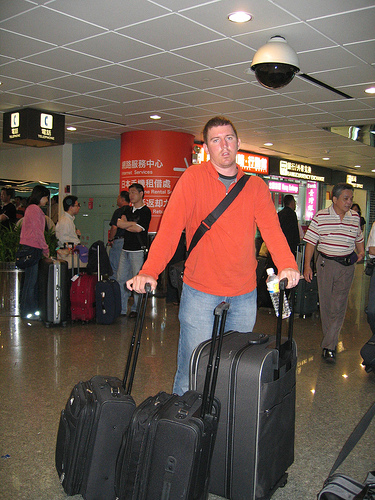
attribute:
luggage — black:
[54, 281, 152, 499]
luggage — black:
[113, 300, 229, 499]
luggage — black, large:
[188, 277, 298, 500]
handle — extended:
[122, 280, 153, 392]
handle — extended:
[199, 300, 229, 420]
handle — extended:
[274, 278, 297, 353]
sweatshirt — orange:
[137, 158, 299, 298]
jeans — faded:
[172, 282, 258, 396]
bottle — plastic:
[265, 267, 290, 320]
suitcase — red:
[67, 247, 98, 324]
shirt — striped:
[301, 205, 367, 257]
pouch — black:
[319, 250, 359, 266]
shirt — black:
[116, 203, 152, 252]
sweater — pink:
[18, 201, 51, 251]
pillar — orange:
[117, 129, 194, 297]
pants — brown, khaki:
[315, 253, 355, 350]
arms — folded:
[115, 205, 152, 233]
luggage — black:
[38, 256, 70, 327]